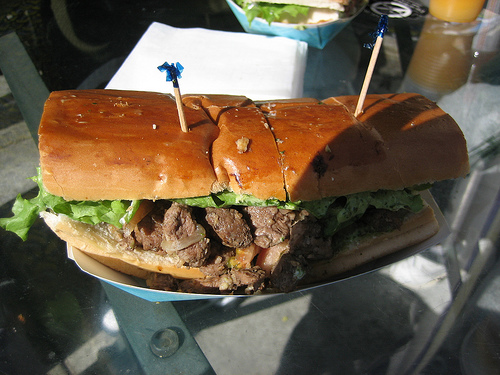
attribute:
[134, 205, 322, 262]
meat — big 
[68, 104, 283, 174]
sandwich — sliced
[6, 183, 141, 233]
lettuce — green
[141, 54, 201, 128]
toothpick — wood